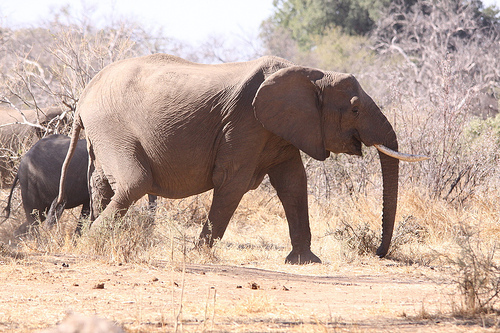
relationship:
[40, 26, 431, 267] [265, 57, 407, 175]
elephant has head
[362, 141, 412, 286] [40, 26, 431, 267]
trunk on elephant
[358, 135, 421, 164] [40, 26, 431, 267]
tusk on elephant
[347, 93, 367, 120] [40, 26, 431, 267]
eye on elephant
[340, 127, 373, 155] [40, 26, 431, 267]
mouth on elephant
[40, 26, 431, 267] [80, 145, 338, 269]
elephant has legs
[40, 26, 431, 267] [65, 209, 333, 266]
elephant has feet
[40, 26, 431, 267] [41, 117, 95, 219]
elephant has tail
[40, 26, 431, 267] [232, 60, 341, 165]
elephant has ear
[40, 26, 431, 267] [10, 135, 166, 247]
elephant near animal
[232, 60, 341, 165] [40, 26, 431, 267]
ear on elephant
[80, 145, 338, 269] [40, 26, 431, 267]
legs on elephant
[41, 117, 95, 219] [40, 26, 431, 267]
tail on elephant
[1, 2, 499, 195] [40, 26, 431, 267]
trees behind elephant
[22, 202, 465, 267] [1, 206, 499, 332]
grass on ground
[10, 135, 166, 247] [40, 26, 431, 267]
animal behind elephant